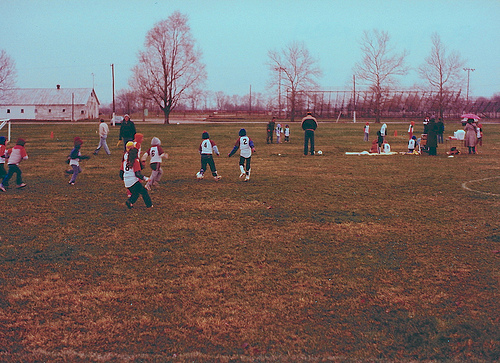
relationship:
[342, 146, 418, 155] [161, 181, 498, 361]
blanket laid on field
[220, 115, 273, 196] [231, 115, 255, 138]
child wearing blue hat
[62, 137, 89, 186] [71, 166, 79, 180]
person in pants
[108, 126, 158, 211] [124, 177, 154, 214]
girl wearing pants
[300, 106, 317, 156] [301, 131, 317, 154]
man wearing pants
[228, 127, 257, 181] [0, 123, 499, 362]
child playing soccer on soccer field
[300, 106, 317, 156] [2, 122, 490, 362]
man standing on soccer field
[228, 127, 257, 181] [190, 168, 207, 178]
child running after soccer ball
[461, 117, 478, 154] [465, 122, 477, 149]
woman in dress jacket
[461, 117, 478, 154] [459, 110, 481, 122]
woman in umbrella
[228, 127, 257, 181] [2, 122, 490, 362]
child on soccer field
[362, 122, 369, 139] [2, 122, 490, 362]
person on soccer field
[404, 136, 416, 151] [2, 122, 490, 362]
person on soccer field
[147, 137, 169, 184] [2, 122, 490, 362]
person on soccer field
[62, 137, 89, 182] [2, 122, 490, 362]
person on soccer field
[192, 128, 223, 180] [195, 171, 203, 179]
child kicking soccer ball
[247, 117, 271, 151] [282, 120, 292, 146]
man and child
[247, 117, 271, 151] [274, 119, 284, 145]
man and child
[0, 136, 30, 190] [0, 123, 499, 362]
child playing in soccer field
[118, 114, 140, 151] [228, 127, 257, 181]
adult walking with child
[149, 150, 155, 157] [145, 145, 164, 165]
6 on shirt